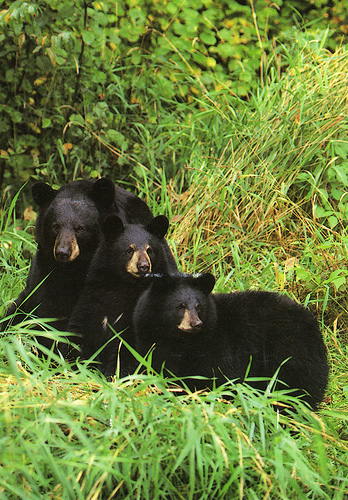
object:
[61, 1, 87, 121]
stem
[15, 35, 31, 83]
stem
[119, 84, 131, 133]
stem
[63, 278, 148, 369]
stomach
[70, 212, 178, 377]
bear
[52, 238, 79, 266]
nose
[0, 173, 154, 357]
bear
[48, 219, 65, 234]
eye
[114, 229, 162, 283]
face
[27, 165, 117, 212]
part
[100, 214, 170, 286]
head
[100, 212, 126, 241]
ear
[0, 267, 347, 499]
grass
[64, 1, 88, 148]
tree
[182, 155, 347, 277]
foilage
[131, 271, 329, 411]
bear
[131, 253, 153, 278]
nose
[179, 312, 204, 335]
nose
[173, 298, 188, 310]
eye